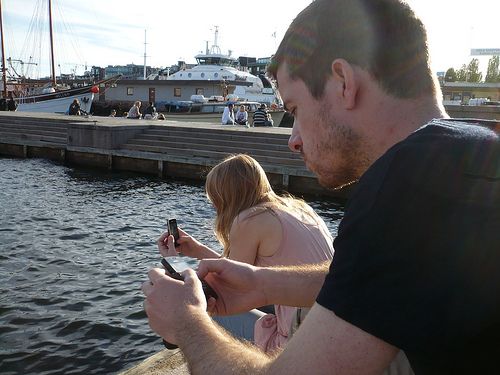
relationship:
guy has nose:
[140, 0, 500, 374] [287, 120, 304, 153]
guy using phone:
[140, 0, 500, 374] [159, 255, 219, 303]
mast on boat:
[6, 2, 8, 87] [4, 75, 103, 115]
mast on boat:
[47, 2, 57, 88] [4, 75, 103, 115]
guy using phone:
[140, 0, 500, 374] [154, 251, 214, 305]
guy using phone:
[140, 0, 500, 374] [153, 245, 222, 327]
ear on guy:
[331, 57, 362, 112] [140, 0, 500, 374]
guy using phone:
[140, 0, 500, 374] [154, 231, 232, 339]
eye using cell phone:
[289, 104, 297, 118] [160, 255, 222, 305]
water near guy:
[0, 146, 345, 374] [140, 0, 500, 374]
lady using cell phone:
[158, 154, 335, 373] [167, 217, 179, 247]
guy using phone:
[166, 0, 486, 375] [155, 229, 220, 313]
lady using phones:
[158, 154, 335, 373] [152, 212, 195, 292]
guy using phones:
[140, 0, 500, 374] [152, 212, 195, 292]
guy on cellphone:
[140, 0, 500, 374] [165, 252, 217, 297]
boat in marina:
[0, 0, 122, 118] [4, 3, 493, 183]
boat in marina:
[0, 0, 127, 118] [2, 2, 300, 178]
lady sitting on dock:
[158, 154, 335, 373] [111, 346, 189, 373]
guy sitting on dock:
[140, 0, 500, 374] [111, 346, 189, 373]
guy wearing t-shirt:
[140, 0, 500, 374] [310, 116, 498, 373]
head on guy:
[266, 0, 442, 188] [140, 0, 500, 374]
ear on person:
[327, 50, 362, 112] [230, 1, 491, 365]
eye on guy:
[289, 104, 297, 118] [140, 0, 500, 374]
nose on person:
[278, 125, 310, 155] [276, 5, 468, 322]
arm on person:
[255, 256, 333, 298] [144, 2, 478, 358]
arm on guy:
[250, 304, 390, 373] [140, 0, 500, 374]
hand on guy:
[132, 260, 212, 361] [140, 0, 500, 374]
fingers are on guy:
[131, 264, 208, 321] [140, 0, 500, 374]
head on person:
[206, 155, 272, 218] [199, 148, 328, 331]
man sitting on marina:
[67, 96, 82, 116] [1, 32, 498, 192]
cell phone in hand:
[167, 217, 179, 247] [165, 227, 195, 253]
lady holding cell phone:
[158, 154, 335, 373] [167, 217, 179, 247]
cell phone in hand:
[161, 251, 221, 302] [141, 267, 210, 345]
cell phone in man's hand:
[161, 251, 221, 302] [191, 255, 260, 319]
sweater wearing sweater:
[312, 115, 498, 373] [253, 107, 273, 123]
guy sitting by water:
[140, 0, 500, 374] [4, 170, 218, 351]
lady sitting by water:
[158, 154, 335, 373] [4, 170, 218, 351]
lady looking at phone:
[158, 154, 335, 373] [160, 213, 183, 245]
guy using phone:
[140, 0, 500, 374] [131, 241, 209, 293]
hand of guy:
[141, 267, 210, 345] [140, 0, 500, 374]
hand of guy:
[154, 229, 211, 283] [140, 0, 500, 374]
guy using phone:
[140, 0, 500, 374] [118, 227, 200, 291]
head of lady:
[178, 150, 332, 303] [221, 102, 239, 125]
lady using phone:
[221, 102, 239, 125] [133, 195, 192, 249]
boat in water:
[141, 22, 281, 132] [0, 146, 345, 374]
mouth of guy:
[302, 154, 314, 172] [140, 0, 500, 374]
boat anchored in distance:
[0, 0, 122, 118] [2, 0, 483, 126]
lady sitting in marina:
[158, 154, 335, 373] [7, 6, 337, 281]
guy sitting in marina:
[140, 0, 500, 374] [7, 6, 337, 281]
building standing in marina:
[92, 81, 242, 107] [2, 51, 484, 370]